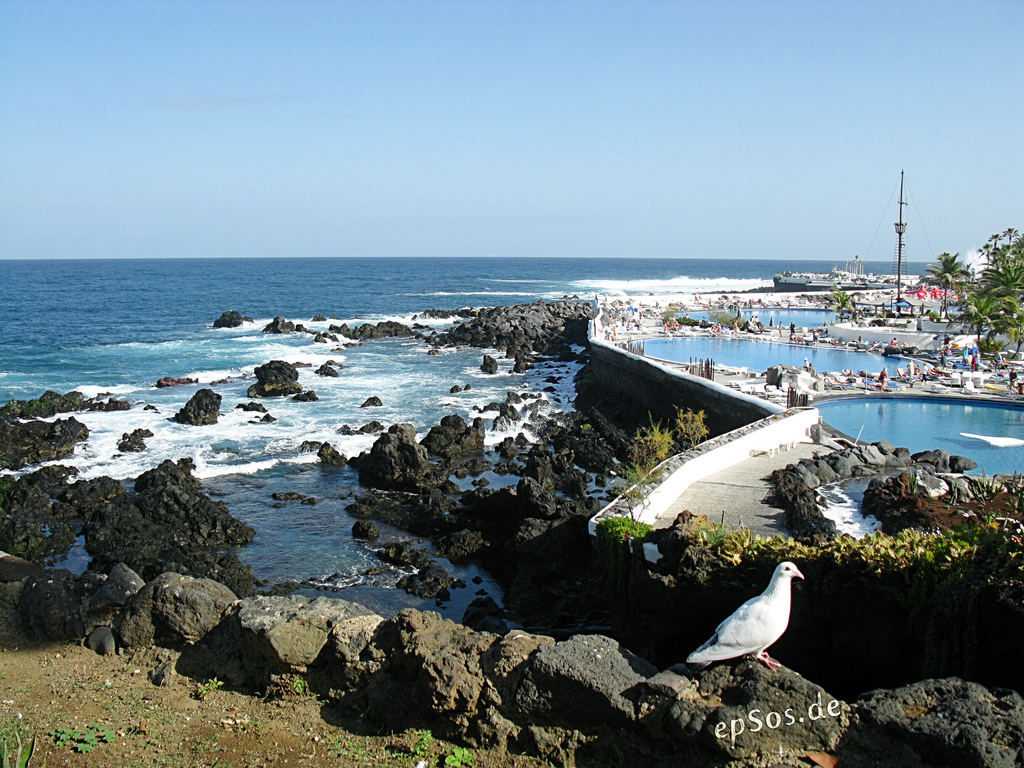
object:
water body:
[14, 258, 835, 615]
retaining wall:
[556, 323, 811, 533]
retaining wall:
[14, 554, 1019, 758]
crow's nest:
[889, 166, 910, 307]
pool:
[830, 390, 1017, 475]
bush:
[658, 514, 1021, 633]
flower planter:
[597, 392, 821, 537]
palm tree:
[925, 241, 972, 328]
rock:
[345, 512, 378, 545]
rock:
[347, 417, 447, 501]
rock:
[419, 406, 484, 471]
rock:
[331, 320, 440, 346]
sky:
[2, 1, 1024, 263]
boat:
[774, 269, 916, 291]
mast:
[892, 165, 919, 278]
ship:
[766, 263, 944, 293]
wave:
[566, 272, 783, 292]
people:
[803, 362, 1022, 401]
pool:
[636, 335, 931, 383]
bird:
[673, 547, 807, 672]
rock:
[243, 354, 304, 400]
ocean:
[5, 255, 939, 625]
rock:
[214, 307, 243, 329]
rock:
[361, 392, 388, 410]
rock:
[353, 423, 443, 498]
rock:
[3, 417, 88, 473]